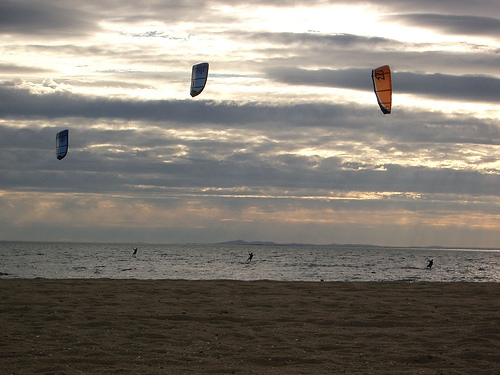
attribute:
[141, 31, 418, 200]
two sails — blue and yellow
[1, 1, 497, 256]
clouds —   white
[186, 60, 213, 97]
kite — striped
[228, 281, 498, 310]
sand —  brown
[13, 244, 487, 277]
water — choppy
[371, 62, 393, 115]
orange kite — triangular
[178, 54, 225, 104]
kite —  high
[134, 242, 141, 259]
person —  at left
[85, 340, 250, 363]
dots — light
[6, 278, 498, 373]
sand — rippled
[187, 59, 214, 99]
sail — blue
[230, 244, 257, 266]
person — in middle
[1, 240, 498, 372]
ocean — gray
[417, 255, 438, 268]
person — at right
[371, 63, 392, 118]
sail — orange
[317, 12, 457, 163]
kite —    in air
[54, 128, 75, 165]
sail —  blue,  in air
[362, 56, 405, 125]
kite —  Orange and black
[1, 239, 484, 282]
water —  of beach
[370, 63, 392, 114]
sail — reddish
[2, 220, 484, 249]
streak — dark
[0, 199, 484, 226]
streak — bright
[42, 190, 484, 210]
streak — dark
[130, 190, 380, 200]
streak — bright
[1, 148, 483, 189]
streak — dark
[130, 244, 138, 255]
figure — tiny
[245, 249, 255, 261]
figure — tiny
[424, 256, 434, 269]
figure — tiny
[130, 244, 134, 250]
arm — lifted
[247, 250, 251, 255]
arm — lifted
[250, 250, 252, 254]
arm — lifted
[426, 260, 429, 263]
arm — lifted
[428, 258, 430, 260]
arm — lifted